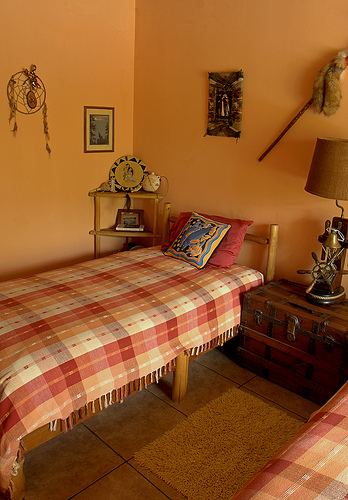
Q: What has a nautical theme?
A: The table lamp.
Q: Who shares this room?
A: Two people.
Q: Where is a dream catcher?
A: On the wall.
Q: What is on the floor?
A: A throw rug.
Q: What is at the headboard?
A: Two pillows.